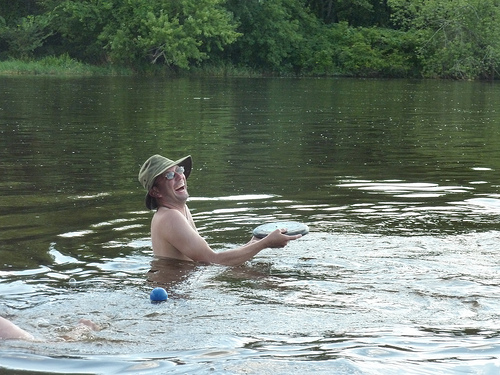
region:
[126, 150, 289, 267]
the man in the water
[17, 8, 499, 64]
trees beside the water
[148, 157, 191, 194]
the man wearing glasses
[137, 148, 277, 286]
the man is smiling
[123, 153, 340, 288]
the man holding the frisbee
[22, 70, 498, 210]
the water is calm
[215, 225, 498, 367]
ripples in the water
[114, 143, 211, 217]
the man wearing the boonie hat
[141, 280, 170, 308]
the ball in the water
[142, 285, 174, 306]
ball is blue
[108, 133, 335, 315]
The man is laughing.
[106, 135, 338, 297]
The man is in the water.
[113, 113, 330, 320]
The man is wearing a hat.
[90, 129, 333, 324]
The man is wearing glasses.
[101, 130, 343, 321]
The man is shirtless.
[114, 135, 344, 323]
The man is holding a frisbee.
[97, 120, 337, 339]
The man is fair-skinned.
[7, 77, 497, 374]
The water is rippling.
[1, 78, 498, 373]
The water is green.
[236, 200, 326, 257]
The frisbee is round.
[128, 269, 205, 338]
The ball is round.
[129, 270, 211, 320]
The ball is blue.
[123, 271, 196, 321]
The ball is in the water.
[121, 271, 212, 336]
The ball is floating.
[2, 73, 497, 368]
The water is calm.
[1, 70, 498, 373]
The water is tranquil.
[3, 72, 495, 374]
The water is serene.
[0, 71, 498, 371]
The water is untroubled.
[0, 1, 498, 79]
The trees are green.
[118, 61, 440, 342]
A person is swimming in the water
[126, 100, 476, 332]
A person is getting very wet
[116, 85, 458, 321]
A person is wearing a hat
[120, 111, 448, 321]
A person is holding a frisbee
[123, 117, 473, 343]
A person is on their day off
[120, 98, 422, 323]
A person is on their vacation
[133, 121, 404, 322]
A person is wearing nice eyeglasses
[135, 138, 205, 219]
A person is smiling very nicely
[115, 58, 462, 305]
A person is out in the daytime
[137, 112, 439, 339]
A person is enjoying their day